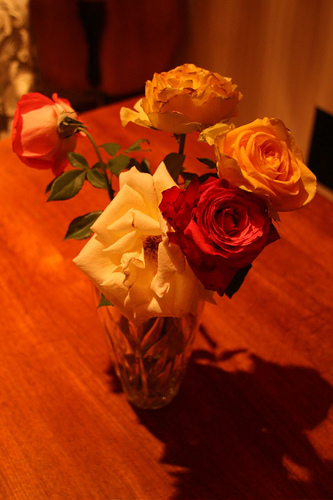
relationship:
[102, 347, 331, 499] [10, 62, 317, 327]
shadow from roses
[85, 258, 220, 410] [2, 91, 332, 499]
vase sitting on table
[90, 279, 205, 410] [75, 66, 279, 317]
vase with rose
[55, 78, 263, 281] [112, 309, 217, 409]
flowers are in vase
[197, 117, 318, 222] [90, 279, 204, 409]
flowers in vase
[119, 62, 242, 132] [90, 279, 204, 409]
flower in vase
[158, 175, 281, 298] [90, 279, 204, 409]
flower in vase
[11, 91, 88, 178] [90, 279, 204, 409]
flower in vase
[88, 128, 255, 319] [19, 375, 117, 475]
flowers on table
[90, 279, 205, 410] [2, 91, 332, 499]
vase on table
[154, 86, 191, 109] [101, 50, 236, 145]
petal on flower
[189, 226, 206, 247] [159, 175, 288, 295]
petal on flower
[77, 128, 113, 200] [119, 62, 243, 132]
stem on flower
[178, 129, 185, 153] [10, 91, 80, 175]
stem on flower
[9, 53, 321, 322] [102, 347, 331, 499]
flower has shadow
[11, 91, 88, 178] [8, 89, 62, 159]
flower has petal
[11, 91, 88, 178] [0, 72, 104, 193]
flower seen behind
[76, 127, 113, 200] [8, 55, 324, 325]
rose stem in group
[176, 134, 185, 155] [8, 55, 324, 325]
rose stem in group